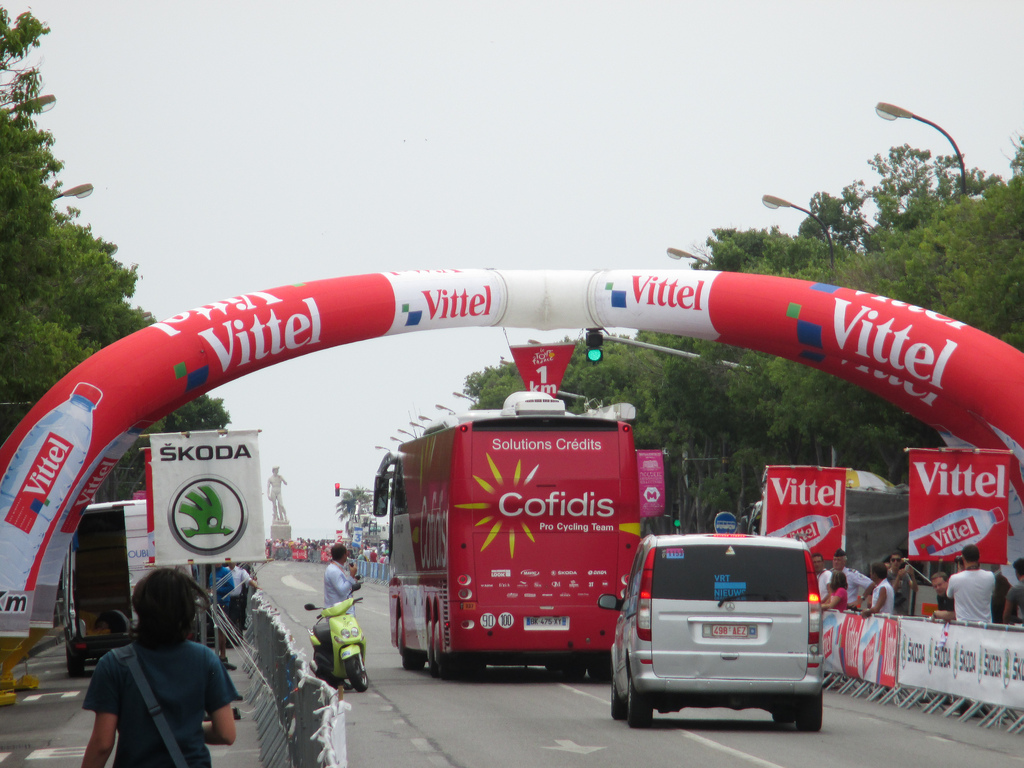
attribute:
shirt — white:
[834, 560, 882, 641]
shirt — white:
[805, 536, 918, 677]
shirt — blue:
[80, 627, 236, 764]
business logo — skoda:
[132, 404, 264, 577]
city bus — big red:
[354, 387, 687, 683]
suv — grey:
[583, 519, 843, 733]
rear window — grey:
[628, 521, 829, 608]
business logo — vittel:
[924, 432, 1022, 560]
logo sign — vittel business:
[175, 284, 320, 395]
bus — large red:
[386, 370, 628, 764]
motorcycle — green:
[293, 575, 415, 705]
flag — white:
[132, 420, 275, 580]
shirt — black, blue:
[83, 644, 241, 766]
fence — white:
[833, 616, 1022, 718]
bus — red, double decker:
[373, 394, 646, 665]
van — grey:
[599, 528, 826, 721]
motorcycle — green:
[308, 595, 367, 688]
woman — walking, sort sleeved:
[77, 566, 244, 757]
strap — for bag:
[113, 640, 191, 757]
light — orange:
[809, 579, 825, 618]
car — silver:
[599, 526, 828, 723]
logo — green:
[178, 471, 235, 538]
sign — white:
[150, 428, 261, 560]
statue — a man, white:
[263, 465, 296, 548]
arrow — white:
[548, 729, 598, 766]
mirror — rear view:
[368, 467, 397, 522]